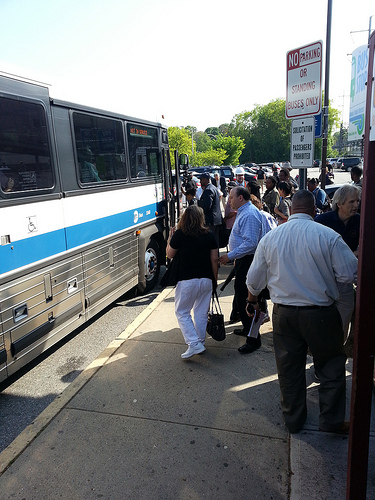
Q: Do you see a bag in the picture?
A: Yes, there is a bag.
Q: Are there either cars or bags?
A: Yes, there is a bag.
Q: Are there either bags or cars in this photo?
A: Yes, there is a bag.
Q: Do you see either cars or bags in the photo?
A: Yes, there is a bag.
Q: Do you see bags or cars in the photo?
A: Yes, there is a bag.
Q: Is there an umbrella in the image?
A: No, there are no umbrellas.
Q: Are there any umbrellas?
A: No, there are no umbrellas.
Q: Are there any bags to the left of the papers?
A: Yes, there is a bag to the left of the papers.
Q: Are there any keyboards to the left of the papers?
A: No, there is a bag to the left of the papers.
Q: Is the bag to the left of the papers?
A: Yes, the bag is to the left of the papers.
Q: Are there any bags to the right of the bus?
A: Yes, there is a bag to the right of the bus.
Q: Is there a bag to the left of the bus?
A: No, the bag is to the right of the bus.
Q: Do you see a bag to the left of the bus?
A: No, the bag is to the right of the bus.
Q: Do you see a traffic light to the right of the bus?
A: No, there is a bag to the right of the bus.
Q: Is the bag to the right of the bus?
A: Yes, the bag is to the right of the bus.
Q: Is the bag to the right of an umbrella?
A: No, the bag is to the right of the bus.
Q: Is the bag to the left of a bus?
A: No, the bag is to the right of a bus.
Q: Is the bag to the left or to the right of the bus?
A: The bag is to the right of the bus.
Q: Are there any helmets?
A: No, there are no helmets.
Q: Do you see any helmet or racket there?
A: No, there are no helmets or rackets.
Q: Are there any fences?
A: No, there are no fences.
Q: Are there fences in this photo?
A: No, there are no fences.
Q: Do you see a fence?
A: No, there are no fences.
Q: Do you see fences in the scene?
A: No, there are no fences.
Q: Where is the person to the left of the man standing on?
A: The person is standing on the sidewalk.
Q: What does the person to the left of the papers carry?
A: The person carries a bag.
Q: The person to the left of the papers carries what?
A: The person carries a bag.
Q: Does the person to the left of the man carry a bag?
A: Yes, the person carries a bag.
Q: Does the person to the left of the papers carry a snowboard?
A: No, the person carries a bag.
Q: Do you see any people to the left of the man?
A: Yes, there is a person to the left of the man.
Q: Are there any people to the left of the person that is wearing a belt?
A: Yes, there is a person to the left of the man.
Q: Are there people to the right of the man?
A: No, the person is to the left of the man.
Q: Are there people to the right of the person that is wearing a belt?
A: No, the person is to the left of the man.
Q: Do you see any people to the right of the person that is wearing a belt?
A: No, the person is to the left of the man.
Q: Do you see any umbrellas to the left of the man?
A: No, there is a person to the left of the man.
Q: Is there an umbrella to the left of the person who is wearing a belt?
A: No, there is a person to the left of the man.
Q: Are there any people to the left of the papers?
A: Yes, there is a person to the left of the papers.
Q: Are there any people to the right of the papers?
A: No, the person is to the left of the papers.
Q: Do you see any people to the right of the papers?
A: No, the person is to the left of the papers.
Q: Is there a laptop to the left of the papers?
A: No, there is a person to the left of the papers.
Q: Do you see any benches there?
A: No, there are no benches.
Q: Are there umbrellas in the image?
A: No, there are no umbrellas.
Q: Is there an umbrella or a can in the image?
A: No, there are no umbrellas or cans.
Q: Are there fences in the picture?
A: No, there are no fences.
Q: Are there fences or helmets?
A: No, there are no fences or helmets.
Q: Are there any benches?
A: No, there are no benches.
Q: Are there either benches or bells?
A: No, there are no benches or bells.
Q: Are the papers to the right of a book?
A: No, the papers are to the right of the bus.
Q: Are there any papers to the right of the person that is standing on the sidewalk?
A: Yes, there are papers to the right of the person.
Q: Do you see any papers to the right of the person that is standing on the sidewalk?
A: Yes, there are papers to the right of the person.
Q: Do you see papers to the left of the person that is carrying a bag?
A: No, the papers are to the right of the person.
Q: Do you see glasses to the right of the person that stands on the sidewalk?
A: No, there are papers to the right of the person.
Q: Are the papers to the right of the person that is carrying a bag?
A: Yes, the papers are to the right of the person.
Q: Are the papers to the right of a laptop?
A: No, the papers are to the right of the person.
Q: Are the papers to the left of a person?
A: No, the papers are to the right of a person.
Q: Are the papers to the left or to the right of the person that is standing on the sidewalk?
A: The papers are to the right of the person.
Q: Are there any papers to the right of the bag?
A: Yes, there are papers to the right of the bag.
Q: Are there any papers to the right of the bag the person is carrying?
A: Yes, there are papers to the right of the bag.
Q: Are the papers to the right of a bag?
A: Yes, the papers are to the right of a bag.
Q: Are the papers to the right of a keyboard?
A: No, the papers are to the right of a bag.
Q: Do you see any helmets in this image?
A: No, there are no helmets.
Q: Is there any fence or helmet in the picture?
A: No, there are no helmets or fences.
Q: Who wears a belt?
A: The man wears a belt.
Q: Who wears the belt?
A: The man wears a belt.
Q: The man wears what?
A: The man wears a belt.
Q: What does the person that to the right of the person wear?
A: The man wears a belt.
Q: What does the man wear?
A: The man wears a belt.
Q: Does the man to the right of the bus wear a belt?
A: Yes, the man wears a belt.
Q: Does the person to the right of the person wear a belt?
A: Yes, the man wears a belt.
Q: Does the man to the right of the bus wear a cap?
A: No, the man wears a belt.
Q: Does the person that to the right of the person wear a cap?
A: No, the man wears a belt.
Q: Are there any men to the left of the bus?
A: No, the man is to the right of the bus.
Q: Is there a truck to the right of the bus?
A: No, there is a man to the right of the bus.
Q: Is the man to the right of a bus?
A: Yes, the man is to the right of a bus.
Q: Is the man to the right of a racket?
A: No, the man is to the right of a bus.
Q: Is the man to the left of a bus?
A: No, the man is to the right of a bus.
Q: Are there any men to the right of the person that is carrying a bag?
A: Yes, there is a man to the right of the person.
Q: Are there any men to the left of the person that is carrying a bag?
A: No, the man is to the right of the person.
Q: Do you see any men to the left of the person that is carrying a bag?
A: No, the man is to the right of the person.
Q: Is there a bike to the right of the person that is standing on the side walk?
A: No, there is a man to the right of the person.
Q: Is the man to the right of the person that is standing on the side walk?
A: Yes, the man is to the right of the person.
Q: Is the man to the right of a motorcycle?
A: No, the man is to the right of the person.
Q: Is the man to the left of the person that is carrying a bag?
A: No, the man is to the right of the person.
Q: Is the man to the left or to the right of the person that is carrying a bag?
A: The man is to the right of the person.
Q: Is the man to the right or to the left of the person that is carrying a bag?
A: The man is to the right of the person.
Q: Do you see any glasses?
A: No, there are no glasses.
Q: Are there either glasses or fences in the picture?
A: No, there are no glasses or fences.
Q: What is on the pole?
A: The sign is on the pole.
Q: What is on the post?
A: The sign is on the post.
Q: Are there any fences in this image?
A: No, there are no fences.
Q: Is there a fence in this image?
A: No, there are no fences.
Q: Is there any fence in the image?
A: No, there are no fences.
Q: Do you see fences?
A: No, there are no fences.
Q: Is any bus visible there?
A: Yes, there is a bus.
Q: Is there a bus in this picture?
A: Yes, there is a bus.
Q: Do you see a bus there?
A: Yes, there is a bus.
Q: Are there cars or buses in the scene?
A: Yes, there is a bus.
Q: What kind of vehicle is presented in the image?
A: The vehicle is a bus.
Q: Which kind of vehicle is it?
A: The vehicle is a bus.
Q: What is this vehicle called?
A: That is a bus.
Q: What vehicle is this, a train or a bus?
A: That is a bus.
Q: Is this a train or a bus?
A: This is a bus.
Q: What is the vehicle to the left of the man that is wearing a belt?
A: The vehicle is a bus.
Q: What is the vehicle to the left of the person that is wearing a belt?
A: The vehicle is a bus.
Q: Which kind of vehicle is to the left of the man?
A: The vehicle is a bus.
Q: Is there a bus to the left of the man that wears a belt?
A: Yes, there is a bus to the left of the man.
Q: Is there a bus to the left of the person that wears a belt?
A: Yes, there is a bus to the left of the man.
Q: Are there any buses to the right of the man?
A: No, the bus is to the left of the man.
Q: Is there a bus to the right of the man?
A: No, the bus is to the left of the man.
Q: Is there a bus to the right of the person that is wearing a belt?
A: No, the bus is to the left of the man.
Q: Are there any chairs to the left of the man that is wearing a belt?
A: No, there is a bus to the left of the man.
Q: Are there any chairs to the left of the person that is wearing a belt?
A: No, there is a bus to the left of the man.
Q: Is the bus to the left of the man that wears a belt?
A: Yes, the bus is to the left of the man.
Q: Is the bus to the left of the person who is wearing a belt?
A: Yes, the bus is to the left of the man.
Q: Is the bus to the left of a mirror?
A: No, the bus is to the left of the man.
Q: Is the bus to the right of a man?
A: No, the bus is to the left of a man.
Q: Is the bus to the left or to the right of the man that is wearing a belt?
A: The bus is to the left of the man.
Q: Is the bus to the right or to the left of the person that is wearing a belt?
A: The bus is to the left of the man.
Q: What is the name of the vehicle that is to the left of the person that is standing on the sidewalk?
A: The vehicle is a bus.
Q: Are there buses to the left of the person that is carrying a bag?
A: Yes, there is a bus to the left of the person.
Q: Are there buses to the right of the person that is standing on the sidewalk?
A: No, the bus is to the left of the person.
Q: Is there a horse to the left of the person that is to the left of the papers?
A: No, there is a bus to the left of the person.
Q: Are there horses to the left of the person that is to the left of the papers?
A: No, there is a bus to the left of the person.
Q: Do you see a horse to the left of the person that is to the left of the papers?
A: No, there is a bus to the left of the person.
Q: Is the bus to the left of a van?
A: No, the bus is to the left of the person.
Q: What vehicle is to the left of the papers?
A: The vehicle is a bus.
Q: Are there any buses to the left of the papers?
A: Yes, there is a bus to the left of the papers.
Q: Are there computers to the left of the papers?
A: No, there is a bus to the left of the papers.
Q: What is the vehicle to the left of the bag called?
A: The vehicle is a bus.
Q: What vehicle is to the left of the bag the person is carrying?
A: The vehicle is a bus.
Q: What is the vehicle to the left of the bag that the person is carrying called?
A: The vehicle is a bus.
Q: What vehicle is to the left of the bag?
A: The vehicle is a bus.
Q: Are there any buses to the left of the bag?
A: Yes, there is a bus to the left of the bag.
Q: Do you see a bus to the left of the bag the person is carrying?
A: Yes, there is a bus to the left of the bag.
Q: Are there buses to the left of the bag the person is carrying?
A: Yes, there is a bus to the left of the bag.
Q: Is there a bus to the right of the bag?
A: No, the bus is to the left of the bag.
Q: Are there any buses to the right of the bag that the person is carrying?
A: No, the bus is to the left of the bag.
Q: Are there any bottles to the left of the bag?
A: No, there is a bus to the left of the bag.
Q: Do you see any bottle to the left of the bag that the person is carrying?
A: No, there is a bus to the left of the bag.